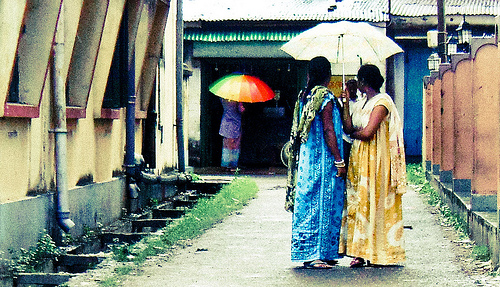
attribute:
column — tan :
[21, 0, 62, 105]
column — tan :
[428, 67, 464, 189]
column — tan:
[414, 40, 495, 236]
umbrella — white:
[279, 19, 404, 109]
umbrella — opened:
[184, 69, 288, 109]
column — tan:
[461, 32, 496, 209]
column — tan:
[418, 74, 435, 174]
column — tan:
[148, 37, 240, 176]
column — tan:
[469, 44, 485, 184]